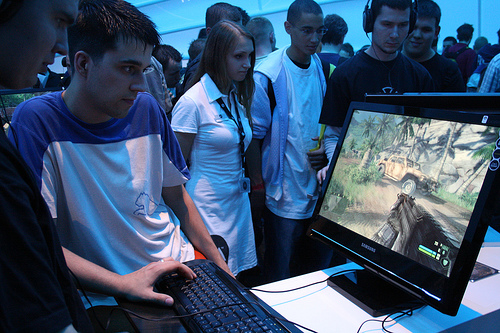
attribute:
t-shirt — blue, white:
[8, 94, 238, 266]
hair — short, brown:
[66, 0, 164, 74]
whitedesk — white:
[252, 249, 499, 331]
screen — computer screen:
[300, 94, 485, 299]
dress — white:
[168, 74, 260, 271]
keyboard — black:
[157, 251, 309, 329]